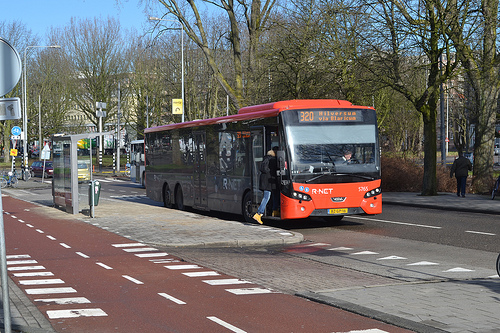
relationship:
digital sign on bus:
[299, 111, 357, 121] [145, 100, 383, 225]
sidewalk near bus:
[381, 190, 500, 214] [145, 100, 383, 225]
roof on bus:
[143, 100, 376, 134] [145, 100, 383, 225]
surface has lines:
[0, 195, 419, 332] [1, 209, 388, 332]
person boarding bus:
[252, 150, 281, 225] [145, 100, 383, 225]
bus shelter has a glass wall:
[51, 132, 114, 219] [73, 138, 93, 217]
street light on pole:
[147, 16, 161, 22] [159, 18, 185, 123]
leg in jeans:
[258, 189, 271, 215] [257, 190, 272, 215]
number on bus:
[301, 111, 315, 121] [145, 100, 383, 225]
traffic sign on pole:
[171, 98, 183, 114] [159, 18, 185, 123]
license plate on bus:
[329, 207, 349, 214] [145, 100, 383, 225]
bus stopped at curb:
[145, 100, 383, 225] [76, 192, 304, 248]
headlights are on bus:
[294, 188, 381, 212] [145, 100, 383, 225]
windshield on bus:
[284, 125, 381, 183] [145, 100, 383, 225]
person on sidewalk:
[450, 153, 471, 197] [381, 190, 500, 214]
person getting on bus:
[252, 150, 281, 225] [145, 100, 383, 225]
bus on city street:
[145, 100, 383, 225] [0, 166, 499, 332]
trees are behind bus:
[0, 1, 499, 197] [145, 100, 383, 225]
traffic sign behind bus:
[171, 98, 183, 114] [145, 100, 383, 225]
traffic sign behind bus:
[10, 125, 22, 135] [145, 100, 383, 225]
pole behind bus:
[159, 18, 185, 123] [145, 100, 383, 225]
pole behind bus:
[23, 46, 51, 171] [145, 100, 383, 225]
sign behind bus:
[9, 148, 18, 156] [145, 100, 383, 225]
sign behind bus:
[40, 143, 50, 161] [145, 100, 383, 225]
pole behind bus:
[116, 81, 120, 174] [145, 100, 383, 225]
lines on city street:
[2, 178, 499, 332] [0, 166, 499, 332]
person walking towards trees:
[450, 153, 471, 197] [0, 1, 499, 197]